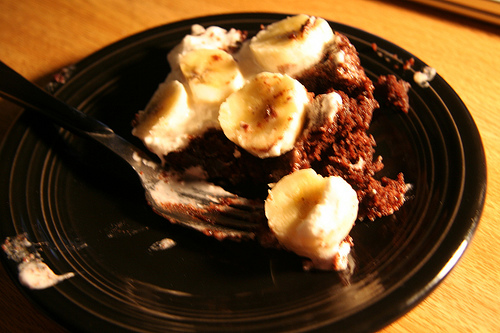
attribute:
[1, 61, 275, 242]
fork — dirty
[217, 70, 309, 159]
food — white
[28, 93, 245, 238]
spon — black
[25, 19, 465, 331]
ripples — Black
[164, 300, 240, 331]
ripples — Black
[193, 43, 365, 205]
food — Yellow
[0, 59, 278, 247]
spoon — black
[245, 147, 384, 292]
banana — sliced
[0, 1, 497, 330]
table — wood, grain, brown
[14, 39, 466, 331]
plate — black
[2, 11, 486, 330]
plate — black, round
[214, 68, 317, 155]
food — Yellow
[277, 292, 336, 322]
ripples — Black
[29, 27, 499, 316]
plate — Yellow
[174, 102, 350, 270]
food — yellow